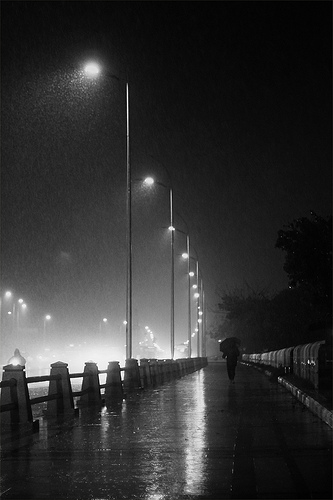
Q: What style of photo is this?
A: Black and white.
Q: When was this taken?
A: At night.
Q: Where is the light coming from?
A: Street lights.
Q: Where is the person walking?
A: Sidewalk.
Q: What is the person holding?
A: Umbrella.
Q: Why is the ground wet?
A: Raining.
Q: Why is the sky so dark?
A: Late night.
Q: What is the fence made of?
A: Cement and wood.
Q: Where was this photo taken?
A: The pier.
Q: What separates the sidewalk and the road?
A: A barrier.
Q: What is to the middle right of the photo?
A: Trees.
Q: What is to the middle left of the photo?
A: Lights.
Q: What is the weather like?
A: Rainy.